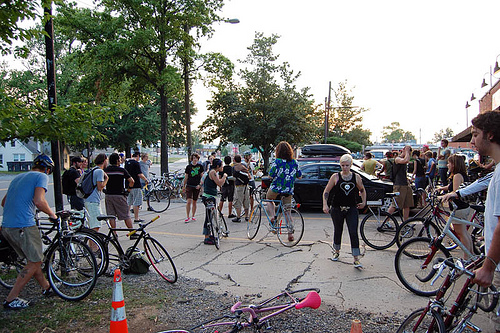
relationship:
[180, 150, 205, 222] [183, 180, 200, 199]
person wearing shorts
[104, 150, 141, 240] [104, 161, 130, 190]
man wearing shirt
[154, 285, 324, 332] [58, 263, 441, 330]
bicycle laying in gravel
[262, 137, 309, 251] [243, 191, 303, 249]
man sitting on bike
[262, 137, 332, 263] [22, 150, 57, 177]
man wearing helmet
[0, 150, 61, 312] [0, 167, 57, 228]
man has shirt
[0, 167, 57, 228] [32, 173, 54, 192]
shirt has sleeve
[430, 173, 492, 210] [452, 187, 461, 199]
person wears watch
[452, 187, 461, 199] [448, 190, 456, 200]
watch on wrist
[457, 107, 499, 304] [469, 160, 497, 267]
man wears shirt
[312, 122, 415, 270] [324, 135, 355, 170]
woman has hair